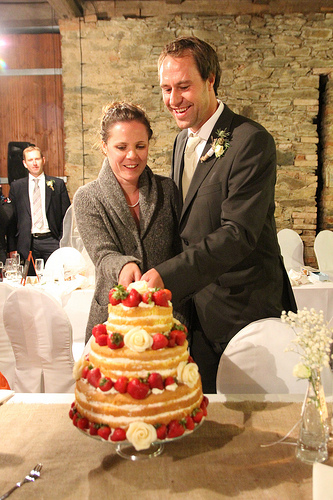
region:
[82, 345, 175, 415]
Red strawberries around cake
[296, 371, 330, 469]
Clear vase on table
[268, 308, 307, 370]
White flowers in vase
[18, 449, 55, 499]
Silver fork sitting on table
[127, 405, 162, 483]
White rose on cake near strawberries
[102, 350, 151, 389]
White filling in between cake pieces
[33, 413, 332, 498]
Tan table runner on table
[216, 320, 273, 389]
White chair cover on chair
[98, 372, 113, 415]
Green stem on strawberry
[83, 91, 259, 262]
Two people cutting cake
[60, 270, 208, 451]
The cake the people are cutting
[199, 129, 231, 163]
The flower on the man's coat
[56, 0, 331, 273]
The stone wall behind the couple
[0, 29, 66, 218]
The wood portion of the wall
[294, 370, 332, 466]
The vase next to the cake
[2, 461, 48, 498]
The fork on the table next to the cake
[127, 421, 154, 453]
The white rose on the bottom layer of cake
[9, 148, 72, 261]
The man in the background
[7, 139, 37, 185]
The speaker behind the man in the background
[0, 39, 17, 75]
The light shown in the background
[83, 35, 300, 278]
this are couples in the photo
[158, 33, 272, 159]
the man is smiling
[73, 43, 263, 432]
the couples are cutting the cake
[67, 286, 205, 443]
this is a cake in front of the couple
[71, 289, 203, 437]
the cake is brown and red in color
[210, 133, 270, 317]
the suit is black in color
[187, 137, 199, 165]
the tie is white in color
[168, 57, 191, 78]
the man is light skinned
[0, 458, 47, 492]
the fork is on the table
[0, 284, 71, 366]
the chair is white in color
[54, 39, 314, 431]
People cutting a cake.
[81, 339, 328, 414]
Strawberries on the cake.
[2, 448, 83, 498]
Fork on the table.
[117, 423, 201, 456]
White flower on the cake.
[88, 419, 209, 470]
Stand for the cake.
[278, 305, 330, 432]
White flowers in the vase.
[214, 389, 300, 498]
Table with cake on it.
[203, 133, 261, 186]
Flower on man's suit.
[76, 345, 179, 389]
Cake with frosting on it.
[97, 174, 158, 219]
Necklace on the woman.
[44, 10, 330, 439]
Couple cutting cake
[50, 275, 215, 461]
three tiered cake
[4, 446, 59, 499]
fork on table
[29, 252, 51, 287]
drinking glass on table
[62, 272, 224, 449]
cake with whole strawberries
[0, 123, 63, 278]
a man behind couple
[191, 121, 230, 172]
flower pinned to man cutting cake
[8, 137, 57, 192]
flower pinned to man behind couple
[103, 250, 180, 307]
couples hands are touching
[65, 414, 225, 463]
a glass cake stand